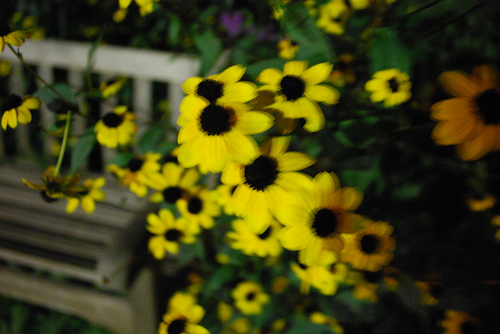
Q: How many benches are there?
A: One.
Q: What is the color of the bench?
A: Brown.